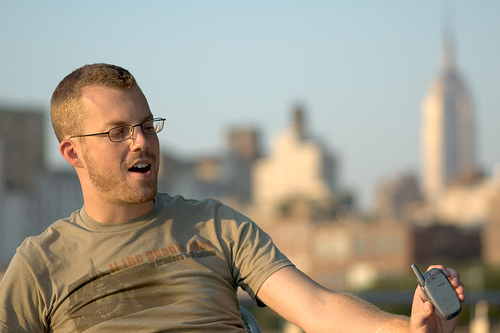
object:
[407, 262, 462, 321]
cellphone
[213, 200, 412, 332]
arm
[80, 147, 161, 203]
beards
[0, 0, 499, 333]
cityscape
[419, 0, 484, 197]
building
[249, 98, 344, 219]
building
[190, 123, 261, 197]
building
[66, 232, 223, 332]
logo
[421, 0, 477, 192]
skycraper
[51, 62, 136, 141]
hair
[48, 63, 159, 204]
head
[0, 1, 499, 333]
city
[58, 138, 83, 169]
ear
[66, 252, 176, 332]
image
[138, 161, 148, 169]
teeth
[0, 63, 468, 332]
guy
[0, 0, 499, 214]
sky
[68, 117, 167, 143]
glasses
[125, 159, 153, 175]
mouth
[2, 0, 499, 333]
background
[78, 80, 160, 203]
face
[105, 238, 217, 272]
words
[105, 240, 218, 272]
letters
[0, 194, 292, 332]
shirt